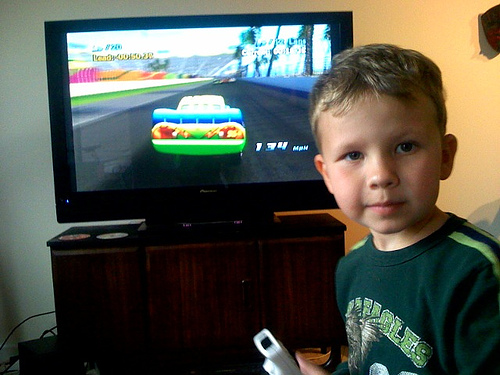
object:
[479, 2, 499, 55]
light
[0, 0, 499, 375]
wall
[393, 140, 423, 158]
eye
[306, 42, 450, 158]
hair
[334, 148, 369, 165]
eye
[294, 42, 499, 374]
boy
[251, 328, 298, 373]
remote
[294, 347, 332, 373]
hand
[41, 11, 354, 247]
tv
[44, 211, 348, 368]
stand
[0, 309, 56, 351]
wire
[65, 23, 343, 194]
tv screen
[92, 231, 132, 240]
discs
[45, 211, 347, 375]
counter